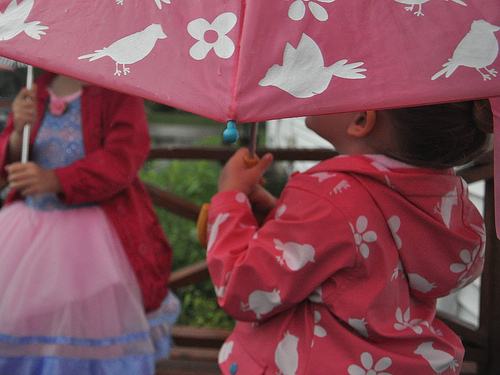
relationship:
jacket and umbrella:
[278, 189, 431, 324] [9, 10, 494, 139]